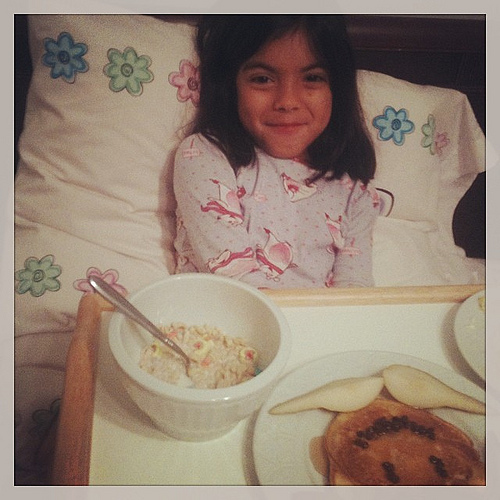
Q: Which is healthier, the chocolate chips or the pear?
A: The pear is healthier than the chocolate chips.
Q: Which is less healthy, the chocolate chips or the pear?
A: The chocolate chips is less healthy than the pear.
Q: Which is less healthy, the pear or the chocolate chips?
A: The chocolate chips is less healthy than the pear.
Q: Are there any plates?
A: Yes, there is a plate.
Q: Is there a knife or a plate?
A: Yes, there is a plate.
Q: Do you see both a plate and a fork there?
A: No, there is a plate but no forks.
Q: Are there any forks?
A: No, there are no forks.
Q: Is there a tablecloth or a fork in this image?
A: No, there are no forks or tablecloths.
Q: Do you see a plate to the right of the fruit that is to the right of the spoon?
A: Yes, there is a plate to the right of the fruit.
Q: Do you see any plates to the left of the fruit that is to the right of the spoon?
A: No, the plate is to the right of the fruit.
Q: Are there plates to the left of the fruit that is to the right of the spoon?
A: No, the plate is to the right of the fruit.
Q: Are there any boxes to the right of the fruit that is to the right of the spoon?
A: No, there is a plate to the right of the fruit.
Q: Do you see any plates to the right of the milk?
A: Yes, there is a plate to the right of the milk.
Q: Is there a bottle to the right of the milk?
A: No, there is a plate to the right of the milk.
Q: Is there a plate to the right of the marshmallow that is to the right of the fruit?
A: Yes, there is a plate to the right of the marshmallow.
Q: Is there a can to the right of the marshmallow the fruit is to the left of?
A: No, there is a plate to the right of the marshmallow.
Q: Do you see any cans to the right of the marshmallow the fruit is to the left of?
A: No, there is a plate to the right of the marshmallow.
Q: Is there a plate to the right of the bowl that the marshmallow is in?
A: Yes, there is a plate to the right of the bowl.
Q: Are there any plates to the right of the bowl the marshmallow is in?
A: Yes, there is a plate to the right of the bowl.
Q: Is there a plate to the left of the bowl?
A: No, the plate is to the right of the bowl.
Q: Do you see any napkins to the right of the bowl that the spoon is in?
A: No, there is a plate to the right of the bowl.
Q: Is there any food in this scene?
A: Yes, there is food.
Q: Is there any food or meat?
A: Yes, there is food.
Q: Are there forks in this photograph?
A: No, there are no forks.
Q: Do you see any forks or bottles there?
A: No, there are no forks or bottles.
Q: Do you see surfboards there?
A: No, there are no surfboards.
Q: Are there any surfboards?
A: No, there are no surfboards.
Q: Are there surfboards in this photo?
A: No, there are no surfboards.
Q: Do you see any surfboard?
A: No, there are no surfboards.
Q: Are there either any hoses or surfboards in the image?
A: No, there are no surfboards or hoses.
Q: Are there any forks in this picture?
A: No, there are no forks.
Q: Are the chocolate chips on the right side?
A: Yes, the chocolate chips are on the right of the image.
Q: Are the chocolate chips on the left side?
A: No, the chocolate chips are on the right of the image.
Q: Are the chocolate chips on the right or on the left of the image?
A: The chocolate chips are on the right of the image.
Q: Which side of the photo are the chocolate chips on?
A: The chocolate chips are on the right of the image.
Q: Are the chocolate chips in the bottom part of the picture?
A: Yes, the chocolate chips are in the bottom of the image.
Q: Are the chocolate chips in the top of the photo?
A: No, the chocolate chips are in the bottom of the image.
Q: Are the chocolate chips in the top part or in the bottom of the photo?
A: The chocolate chips are in the bottom of the image.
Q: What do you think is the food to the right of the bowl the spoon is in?
A: The food is chocolate chips.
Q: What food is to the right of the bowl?
A: The food is chocolate chips.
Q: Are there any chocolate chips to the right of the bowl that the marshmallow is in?
A: Yes, there are chocolate chips to the right of the bowl.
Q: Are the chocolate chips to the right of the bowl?
A: Yes, the chocolate chips are to the right of the bowl.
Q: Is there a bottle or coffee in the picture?
A: No, there are no bottles or coffee.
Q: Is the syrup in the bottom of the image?
A: Yes, the syrup is in the bottom of the image.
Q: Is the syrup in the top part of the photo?
A: No, the syrup is in the bottom of the image.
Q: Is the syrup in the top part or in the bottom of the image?
A: The syrup is in the bottom of the image.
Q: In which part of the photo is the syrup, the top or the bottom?
A: The syrup is in the bottom of the image.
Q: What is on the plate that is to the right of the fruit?
A: The syrup is on the plate.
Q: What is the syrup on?
A: The syrup is on the plate.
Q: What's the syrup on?
A: The syrup is on the plate.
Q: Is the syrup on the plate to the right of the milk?
A: Yes, the syrup is on the plate.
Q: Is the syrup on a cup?
A: No, the syrup is on the plate.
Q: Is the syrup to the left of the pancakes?
A: Yes, the syrup is to the left of the pancakes.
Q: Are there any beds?
A: Yes, there is a bed.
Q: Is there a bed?
A: Yes, there is a bed.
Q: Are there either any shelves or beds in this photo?
A: Yes, there is a bed.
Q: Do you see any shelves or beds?
A: Yes, there is a bed.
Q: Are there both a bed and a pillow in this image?
A: Yes, there are both a bed and a pillow.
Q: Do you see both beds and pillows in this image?
A: Yes, there are both a bed and a pillow.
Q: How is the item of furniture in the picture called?
A: The piece of furniture is a bed.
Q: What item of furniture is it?
A: The piece of furniture is a bed.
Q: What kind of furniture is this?
A: This is a bed.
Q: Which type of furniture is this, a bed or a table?
A: This is a bed.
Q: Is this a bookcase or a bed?
A: This is a bed.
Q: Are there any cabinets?
A: No, there are no cabinets.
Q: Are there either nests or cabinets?
A: No, there are no cabinets or nests.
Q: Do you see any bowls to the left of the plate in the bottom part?
A: Yes, there is a bowl to the left of the plate.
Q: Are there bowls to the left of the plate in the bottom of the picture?
A: Yes, there is a bowl to the left of the plate.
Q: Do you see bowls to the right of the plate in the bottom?
A: No, the bowl is to the left of the plate.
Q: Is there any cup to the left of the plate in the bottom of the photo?
A: No, there is a bowl to the left of the plate.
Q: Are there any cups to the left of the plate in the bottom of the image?
A: No, there is a bowl to the left of the plate.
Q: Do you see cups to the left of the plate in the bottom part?
A: No, there is a bowl to the left of the plate.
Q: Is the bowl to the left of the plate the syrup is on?
A: Yes, the bowl is to the left of the plate.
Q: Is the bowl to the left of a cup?
A: No, the bowl is to the left of the plate.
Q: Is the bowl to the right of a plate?
A: No, the bowl is to the left of a plate.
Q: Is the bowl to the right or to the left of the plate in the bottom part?
A: The bowl is to the left of the plate.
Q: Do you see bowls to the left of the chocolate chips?
A: Yes, there is a bowl to the left of the chocolate chips.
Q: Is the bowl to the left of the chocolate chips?
A: Yes, the bowl is to the left of the chocolate chips.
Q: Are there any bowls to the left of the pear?
A: Yes, there is a bowl to the left of the pear.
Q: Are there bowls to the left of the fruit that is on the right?
A: Yes, there is a bowl to the left of the pear.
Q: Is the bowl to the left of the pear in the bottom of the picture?
A: Yes, the bowl is to the left of the pear.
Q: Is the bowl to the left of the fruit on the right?
A: Yes, the bowl is to the left of the pear.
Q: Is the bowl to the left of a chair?
A: No, the bowl is to the left of the pear.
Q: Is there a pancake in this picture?
A: Yes, there are pancakes.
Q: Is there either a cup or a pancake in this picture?
A: Yes, there are pancakes.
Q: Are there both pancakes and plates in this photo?
A: Yes, there are both pancakes and a plate.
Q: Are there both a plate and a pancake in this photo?
A: Yes, there are both a pancake and a plate.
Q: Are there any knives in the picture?
A: No, there are no knives.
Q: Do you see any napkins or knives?
A: No, there are no knives or napkins.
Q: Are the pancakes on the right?
A: Yes, the pancakes are on the right of the image.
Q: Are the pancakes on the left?
A: No, the pancakes are on the right of the image.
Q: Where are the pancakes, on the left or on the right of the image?
A: The pancakes are on the right of the image.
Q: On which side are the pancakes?
A: The pancakes are on the right of the image.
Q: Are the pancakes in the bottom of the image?
A: Yes, the pancakes are in the bottom of the image.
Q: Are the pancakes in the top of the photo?
A: No, the pancakes are in the bottom of the image.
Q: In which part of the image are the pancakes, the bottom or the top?
A: The pancakes are in the bottom of the image.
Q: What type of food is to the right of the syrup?
A: The food is pancakes.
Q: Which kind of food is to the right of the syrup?
A: The food is pancakes.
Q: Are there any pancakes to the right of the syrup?
A: Yes, there are pancakes to the right of the syrup.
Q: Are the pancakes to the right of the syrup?
A: Yes, the pancakes are to the right of the syrup.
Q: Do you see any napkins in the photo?
A: No, there are no napkins.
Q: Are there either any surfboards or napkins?
A: No, there are no napkins or surfboards.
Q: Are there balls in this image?
A: No, there are no balls.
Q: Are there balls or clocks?
A: No, there are no balls or clocks.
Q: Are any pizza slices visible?
A: No, there are no pizza slices.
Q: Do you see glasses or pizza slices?
A: No, there are no pizza slices or glasses.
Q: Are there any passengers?
A: No, there are no passengers.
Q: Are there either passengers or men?
A: No, there are no passengers or men.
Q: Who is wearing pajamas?
A: The girl is wearing pajamas.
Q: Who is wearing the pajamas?
A: The girl is wearing pajamas.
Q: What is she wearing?
A: The girl is wearing pajamas.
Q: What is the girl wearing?
A: The girl is wearing pajamas.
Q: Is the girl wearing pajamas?
A: Yes, the girl is wearing pajamas.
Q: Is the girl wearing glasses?
A: No, the girl is wearing pajamas.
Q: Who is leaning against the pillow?
A: The girl is leaning against the pillow.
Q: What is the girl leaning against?
A: The girl is leaning against the pillow.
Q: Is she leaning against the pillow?
A: Yes, the girl is leaning against the pillow.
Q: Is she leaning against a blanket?
A: No, the girl is leaning against the pillow.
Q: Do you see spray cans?
A: No, there are no spray cans.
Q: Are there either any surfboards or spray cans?
A: No, there are no spray cans or surfboards.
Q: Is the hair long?
A: Yes, the hair is long.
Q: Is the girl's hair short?
A: No, the hair is long.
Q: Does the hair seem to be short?
A: No, the hair is long.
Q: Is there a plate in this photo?
A: Yes, there is a plate.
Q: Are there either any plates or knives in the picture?
A: Yes, there is a plate.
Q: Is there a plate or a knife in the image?
A: Yes, there is a plate.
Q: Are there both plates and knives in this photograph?
A: No, there is a plate but no knives.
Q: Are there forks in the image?
A: No, there are no forks.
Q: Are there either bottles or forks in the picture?
A: No, there are no forks or bottles.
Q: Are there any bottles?
A: No, there are no bottles.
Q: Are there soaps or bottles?
A: No, there are no bottles or soaps.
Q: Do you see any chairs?
A: No, there are no chairs.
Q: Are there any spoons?
A: Yes, there is a spoon.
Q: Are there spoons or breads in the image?
A: Yes, there is a spoon.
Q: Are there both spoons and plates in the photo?
A: Yes, there are both a spoon and a plate.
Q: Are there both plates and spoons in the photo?
A: Yes, there are both a spoon and a plate.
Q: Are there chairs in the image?
A: No, there are no chairs.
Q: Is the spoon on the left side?
A: Yes, the spoon is on the left of the image.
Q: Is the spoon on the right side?
A: No, the spoon is on the left of the image.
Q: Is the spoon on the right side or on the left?
A: The spoon is on the left of the image.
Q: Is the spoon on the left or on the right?
A: The spoon is on the left of the image.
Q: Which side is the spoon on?
A: The spoon is on the left of the image.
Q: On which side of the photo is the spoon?
A: The spoon is on the left of the image.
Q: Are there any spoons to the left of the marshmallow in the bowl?
A: Yes, there is a spoon to the left of the marshmallow.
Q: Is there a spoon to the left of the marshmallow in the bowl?
A: Yes, there is a spoon to the left of the marshmallow.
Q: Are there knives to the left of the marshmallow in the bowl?
A: No, there is a spoon to the left of the marshmallow.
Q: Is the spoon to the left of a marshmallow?
A: Yes, the spoon is to the left of a marshmallow.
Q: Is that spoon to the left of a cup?
A: No, the spoon is to the left of a marshmallow.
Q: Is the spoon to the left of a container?
A: No, the spoon is to the left of a marshmallow.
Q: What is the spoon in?
A: The spoon is in the bowl.